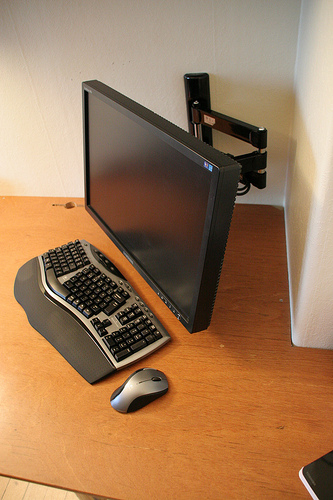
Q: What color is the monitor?
A: Black.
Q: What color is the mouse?
A: Grey.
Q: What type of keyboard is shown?
A: Ergonomic.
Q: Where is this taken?
A: Office.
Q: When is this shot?
A: Daytime.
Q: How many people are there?
A: 0.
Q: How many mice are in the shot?
A: 1.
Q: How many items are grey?
A: 2.